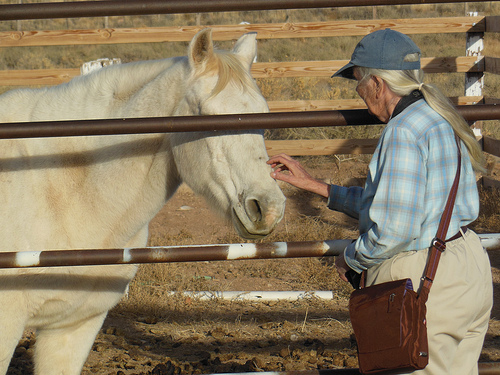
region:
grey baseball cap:
[321, 22, 423, 83]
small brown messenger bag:
[343, 221, 435, 373]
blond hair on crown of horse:
[186, 46, 266, 101]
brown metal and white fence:
[2, 1, 434, 278]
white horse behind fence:
[2, 21, 297, 373]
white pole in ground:
[137, 277, 348, 313]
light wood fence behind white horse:
[0, 12, 435, 174]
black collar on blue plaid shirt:
[377, 86, 431, 121]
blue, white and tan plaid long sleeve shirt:
[325, 85, 435, 275]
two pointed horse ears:
[182, 19, 264, 74]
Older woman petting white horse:
[265, 25, 497, 374]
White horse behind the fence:
[0, 24, 291, 374]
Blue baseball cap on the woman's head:
[328, 25, 425, 81]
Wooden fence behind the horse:
[3, 8, 499, 159]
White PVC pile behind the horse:
[123, 285, 338, 310]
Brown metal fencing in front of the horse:
[0, 0, 497, 269]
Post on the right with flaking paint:
[464, 6, 489, 152]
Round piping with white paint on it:
[0, 230, 497, 272]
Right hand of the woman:
[263, 150, 331, 201]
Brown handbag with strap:
[343, 122, 468, 374]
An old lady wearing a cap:
[265, 21, 493, 371]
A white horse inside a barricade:
[8, 24, 291, 373]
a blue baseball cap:
[329, 26, 426, 80]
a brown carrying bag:
[344, 269, 434, 373]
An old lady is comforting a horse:
[107, 7, 498, 373]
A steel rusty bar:
[1, 102, 498, 144]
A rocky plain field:
[133, 281, 347, 373]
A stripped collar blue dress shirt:
[325, 92, 498, 273]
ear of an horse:
[185, 19, 271, 82]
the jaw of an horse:
[220, 177, 292, 237]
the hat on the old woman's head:
[330, 28, 420, 83]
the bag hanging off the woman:
[347, 113, 462, 374]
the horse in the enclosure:
[0, 27, 286, 374]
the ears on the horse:
[187, 26, 257, 73]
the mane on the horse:
[197, 49, 249, 99]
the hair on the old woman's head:
[357, 41, 488, 175]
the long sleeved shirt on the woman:
[326, 99, 478, 275]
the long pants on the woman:
[363, 227, 493, 374]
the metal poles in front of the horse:
[0, 0, 497, 269]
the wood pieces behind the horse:
[0, 9, 498, 157]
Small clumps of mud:
[112, 344, 146, 365]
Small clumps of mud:
[148, 307, 186, 350]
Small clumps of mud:
[190, 321, 249, 355]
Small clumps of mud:
[253, 325, 295, 353]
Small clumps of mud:
[295, 325, 318, 350]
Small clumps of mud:
[315, 328, 355, 367]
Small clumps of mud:
[276, 359, 334, 374]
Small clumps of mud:
[249, 354, 284, 370]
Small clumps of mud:
[195, 349, 257, 371]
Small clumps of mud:
[143, 347, 229, 374]